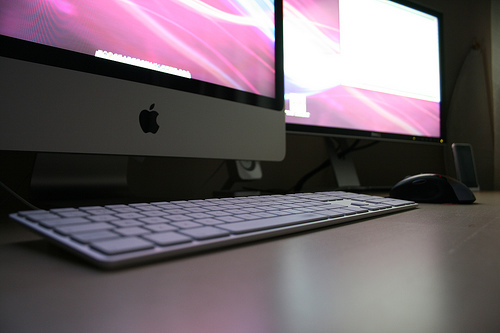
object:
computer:
[0, 0, 477, 270]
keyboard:
[9, 190, 418, 273]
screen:
[0, 0, 286, 110]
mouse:
[389, 173, 476, 204]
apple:
[139, 103, 160, 134]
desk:
[0, 173, 499, 332]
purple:
[283, 85, 441, 139]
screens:
[284, 0, 443, 143]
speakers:
[444, 143, 481, 190]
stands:
[330, 149, 361, 188]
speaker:
[228, 161, 263, 182]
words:
[283, 92, 311, 118]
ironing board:
[448, 47, 494, 187]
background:
[443, 0, 497, 189]